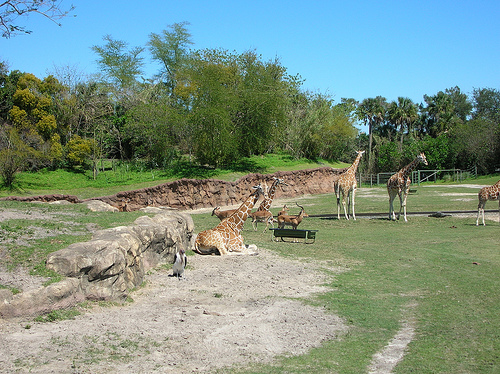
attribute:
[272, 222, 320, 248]
bench — black, tiny, small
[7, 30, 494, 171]
trees — brown, green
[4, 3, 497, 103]
sky — clear, blue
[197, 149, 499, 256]
giraffes — tall, long, standing